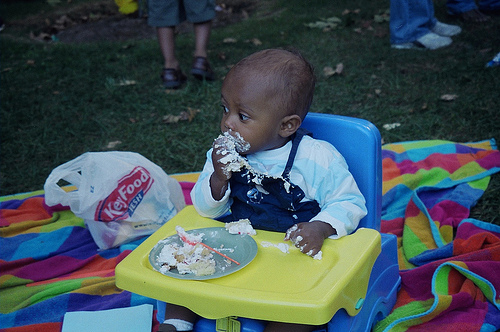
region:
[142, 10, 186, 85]
leg of a person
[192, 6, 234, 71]
leg of a person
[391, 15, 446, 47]
leg of a person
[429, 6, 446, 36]
leg of a person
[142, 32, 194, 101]
a leg of a person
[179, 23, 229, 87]
a leg of a person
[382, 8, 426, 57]
a leg of a person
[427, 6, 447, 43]
a leg of a person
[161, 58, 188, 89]
feet of a person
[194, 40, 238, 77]
feet of a person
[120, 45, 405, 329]
a baby in a seat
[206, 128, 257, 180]
a baby eating food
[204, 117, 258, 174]
a baby with food on his face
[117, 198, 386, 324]
a yellow tray on a high chair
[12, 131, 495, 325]
a beach blanket on the ground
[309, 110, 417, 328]
a blue chair with a baby sitting in it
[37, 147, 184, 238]
a plastic bag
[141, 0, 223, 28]
a person wearing shorts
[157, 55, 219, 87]
shoes on feet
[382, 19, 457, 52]
a person wearing tennis shoes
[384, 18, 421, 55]
leg of a person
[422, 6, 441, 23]
leg of a person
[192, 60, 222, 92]
feet of a person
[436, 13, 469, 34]
feet of a person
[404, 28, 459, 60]
feet of a person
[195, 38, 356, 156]
head of a person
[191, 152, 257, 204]
arm of a person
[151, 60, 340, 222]
baby is eating cake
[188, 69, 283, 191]
baby is eating cake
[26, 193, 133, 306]
the rag is colorful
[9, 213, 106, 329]
the rag is colorful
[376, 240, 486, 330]
the rag is colorful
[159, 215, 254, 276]
cake on gray plate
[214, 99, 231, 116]
right eye on child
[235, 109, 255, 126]
left eye on child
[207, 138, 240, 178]
right hand on child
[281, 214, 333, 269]
left hand on child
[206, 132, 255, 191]
messy cake in child's hand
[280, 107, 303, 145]
left ear on child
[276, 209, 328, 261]
messy cake in child's hand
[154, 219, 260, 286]
gray plate on yellow tray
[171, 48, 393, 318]
child sitting in high chair